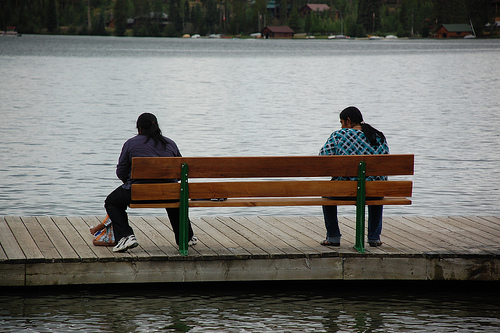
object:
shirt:
[114, 134, 181, 188]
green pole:
[172, 165, 192, 255]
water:
[0, 35, 499, 332]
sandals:
[319, 236, 342, 247]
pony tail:
[360, 121, 385, 145]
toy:
[125, 151, 422, 258]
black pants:
[103, 181, 195, 247]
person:
[101, 111, 203, 254]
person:
[316, 105, 394, 248]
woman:
[316, 106, 389, 248]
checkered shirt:
[316, 128, 390, 181]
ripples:
[0, 294, 499, 332]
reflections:
[3, 287, 496, 330]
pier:
[3, 212, 498, 280]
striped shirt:
[316, 127, 391, 192]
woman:
[103, 112, 198, 253]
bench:
[126, 150, 416, 257]